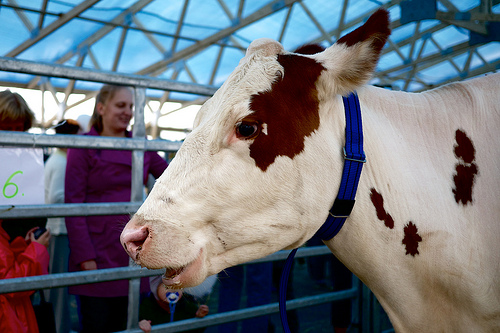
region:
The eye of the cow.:
[230, 118, 265, 140]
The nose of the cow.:
[117, 224, 152, 257]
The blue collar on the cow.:
[312, 83, 369, 248]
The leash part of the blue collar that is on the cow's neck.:
[273, 250, 311, 330]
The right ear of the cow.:
[319, 7, 396, 97]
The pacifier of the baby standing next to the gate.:
[166, 290, 179, 323]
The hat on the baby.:
[147, 273, 163, 296]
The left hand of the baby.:
[139, 317, 151, 330]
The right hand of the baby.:
[195, 307, 205, 317]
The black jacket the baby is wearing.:
[142, 295, 195, 320]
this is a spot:
[433, 122, 487, 169]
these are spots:
[435, 122, 484, 209]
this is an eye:
[220, 118, 270, 146]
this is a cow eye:
[196, 104, 281, 148]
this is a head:
[88, 36, 378, 306]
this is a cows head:
[85, 28, 383, 303]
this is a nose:
[110, 217, 166, 269]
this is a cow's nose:
[100, 208, 173, 270]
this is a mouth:
[126, 230, 228, 310]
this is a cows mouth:
[153, 224, 212, 288]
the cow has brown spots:
[445, 116, 488, 213]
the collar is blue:
[338, 109, 366, 185]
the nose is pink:
[117, 223, 154, 252]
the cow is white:
[191, 162, 263, 203]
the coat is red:
[4, 243, 32, 264]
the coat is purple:
[88, 159, 124, 190]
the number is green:
[2, 165, 30, 205]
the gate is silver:
[16, 124, 96, 154]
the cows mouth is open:
[148, 257, 203, 291]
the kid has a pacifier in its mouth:
[158, 286, 184, 308]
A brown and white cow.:
[118, 5, 497, 326]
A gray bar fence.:
[1, 55, 388, 330]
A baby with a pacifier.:
[138, 273, 208, 330]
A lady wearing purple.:
[64, 83, 168, 328]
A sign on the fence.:
[0, 146, 47, 206]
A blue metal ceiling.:
[1, 0, 498, 102]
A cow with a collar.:
[120, 25, 496, 330]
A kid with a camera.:
[1, 223, 53, 329]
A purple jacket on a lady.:
[65, 128, 170, 298]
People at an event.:
[0, 82, 170, 330]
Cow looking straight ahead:
[120, 7, 498, 329]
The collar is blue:
[277, 91, 364, 331]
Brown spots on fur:
[368, 129, 476, 256]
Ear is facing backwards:
[318, 6, 390, 92]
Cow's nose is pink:
[120, 220, 148, 258]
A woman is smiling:
[65, 82, 168, 331]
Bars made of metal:
[1, 59, 388, 331]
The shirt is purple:
[65, 135, 166, 295]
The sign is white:
[2, 146, 42, 206]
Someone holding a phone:
[1, 227, 53, 331]